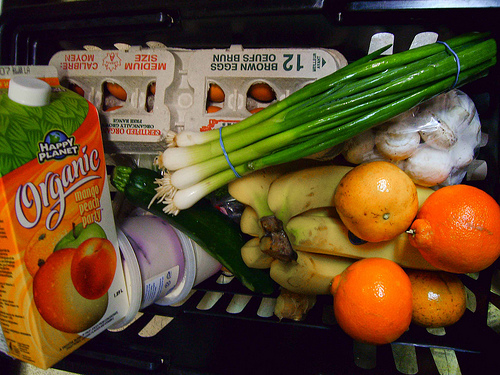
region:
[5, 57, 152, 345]
Carton of orange juice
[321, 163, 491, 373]
Round oranges on a shelf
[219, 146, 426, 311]
Yellow bananas in a basket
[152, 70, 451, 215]
Green onions in a basket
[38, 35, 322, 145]
Brown eggs in a basket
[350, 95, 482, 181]
Mushrooms in a basket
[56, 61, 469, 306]
Food in a basket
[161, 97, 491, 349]
Produce in a basket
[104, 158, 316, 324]
Zuchini in a basket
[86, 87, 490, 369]
Fresh vegetables in a basket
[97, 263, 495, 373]
part of a black shopping basket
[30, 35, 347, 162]
a dozen of brown eggs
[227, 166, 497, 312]
a bundle of yellow bananas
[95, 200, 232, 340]
two tubs of yogurt by the juice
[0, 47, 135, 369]
a carton of fruit juice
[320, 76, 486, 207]
a bag of delicious mushrooms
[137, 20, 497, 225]
a bundle of green onions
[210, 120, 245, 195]
a blue rubber band wrapped around the onion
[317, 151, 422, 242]
a bright and shiny orange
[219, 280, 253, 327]
a hole in shopping basket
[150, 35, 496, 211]
a bunch of green onion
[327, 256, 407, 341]
a tangerine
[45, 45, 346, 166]
a dozen of brown eggs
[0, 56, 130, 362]
a carton of organic peach juice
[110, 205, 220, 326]
two yogurt containers set on the side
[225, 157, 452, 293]
a bunch of bananas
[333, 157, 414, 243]
an orange next to a bunch of bananas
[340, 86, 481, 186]
a bunch of mushrooms in a white plastic bag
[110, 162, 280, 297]
a green zucchini on top of a yogurt container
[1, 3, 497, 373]
a black container containing groceries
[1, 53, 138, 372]
carton of juice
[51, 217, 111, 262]
green apple on a juice carton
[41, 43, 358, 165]
dozen of eggs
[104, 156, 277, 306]
green zuchini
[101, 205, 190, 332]
container of yogurt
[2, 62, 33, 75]
expiration date on a carton of juice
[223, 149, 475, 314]
a bunch of yellow bananas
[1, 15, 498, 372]
groceries in a black plastic basket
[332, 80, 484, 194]
bag of white mushrooms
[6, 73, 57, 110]
white tab on a juice carton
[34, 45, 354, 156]
carton of brown eggs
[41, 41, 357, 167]
carton of one dozen eggs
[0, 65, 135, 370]
carton of orange juice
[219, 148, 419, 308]
a bunch of bananas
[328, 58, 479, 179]
a bag of several white mushrooms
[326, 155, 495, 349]
some oranges and tangerines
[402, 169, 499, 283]
a tangerine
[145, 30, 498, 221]
several ripe wide onions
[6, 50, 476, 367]
several fruits and vegetables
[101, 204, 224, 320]
two plastic containers